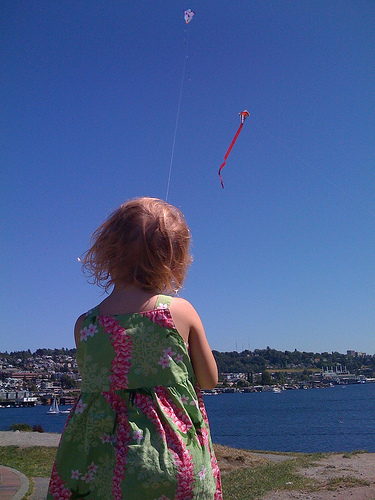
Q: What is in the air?
A: Kite.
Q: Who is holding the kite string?
A: Girl.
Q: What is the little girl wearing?
A: Dress.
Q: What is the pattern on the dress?
A: Floral.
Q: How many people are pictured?
A: 1.